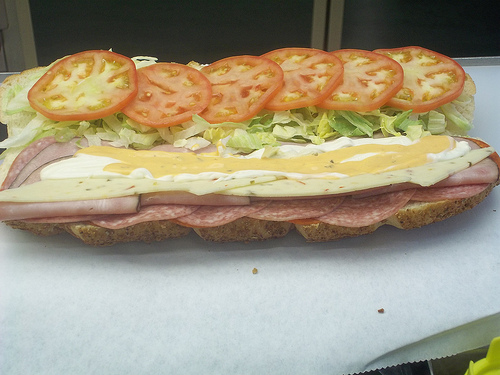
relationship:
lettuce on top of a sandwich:
[56, 115, 446, 128] [6, 32, 498, 291]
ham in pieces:
[9, 193, 478, 196] [6, 183, 156, 223]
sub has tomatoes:
[0, 51, 496, 261] [25, 24, 462, 127]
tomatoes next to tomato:
[25, 49, 135, 125] [116, 60, 217, 128]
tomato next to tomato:
[116, 60, 217, 128] [196, 49, 284, 133]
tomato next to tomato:
[196, 49, 284, 133] [260, 43, 342, 113]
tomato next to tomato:
[260, 43, 342, 113] [314, 36, 408, 122]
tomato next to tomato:
[314, 36, 408, 122] [374, 34, 474, 118]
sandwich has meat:
[6, 32, 498, 291] [18, 147, 500, 233]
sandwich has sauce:
[6, 32, 498, 291] [17, 137, 470, 166]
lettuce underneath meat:
[56, 115, 446, 128] [18, 147, 500, 233]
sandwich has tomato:
[6, 32, 498, 291] [374, 34, 474, 118]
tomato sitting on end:
[374, 34, 474, 118] [387, 27, 491, 208]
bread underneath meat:
[6, 135, 495, 254] [18, 147, 500, 233]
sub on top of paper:
[0, 51, 496, 261] [9, 59, 498, 374]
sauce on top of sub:
[17, 137, 470, 166] [0, 51, 496, 261]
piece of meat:
[9, 141, 144, 210] [18, 147, 500, 233]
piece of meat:
[143, 137, 264, 203] [18, 147, 500, 233]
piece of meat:
[351, 134, 491, 198] [18, 147, 500, 233]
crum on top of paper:
[229, 259, 307, 289] [9, 59, 498, 374]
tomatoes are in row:
[25, 24, 462, 127] [32, 39, 463, 129]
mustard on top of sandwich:
[95, 143, 462, 182] [6, 32, 498, 291]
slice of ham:
[12, 143, 139, 216] [9, 193, 478, 196]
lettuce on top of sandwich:
[56, 115, 446, 128] [6, 32, 498, 291]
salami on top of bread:
[34, 190, 480, 230] [6, 135, 495, 254]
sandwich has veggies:
[6, 32, 498, 291] [32, 55, 465, 135]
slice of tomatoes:
[29, 47, 143, 127] [25, 49, 135, 125]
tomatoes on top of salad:
[25, 49, 135, 125] [15, 72, 467, 135]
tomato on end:
[374, 34, 474, 118] [387, 27, 491, 208]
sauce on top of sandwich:
[17, 137, 470, 166] [6, 32, 498, 291]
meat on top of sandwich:
[18, 147, 500, 233] [6, 32, 498, 291]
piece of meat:
[249, 147, 365, 198] [18, 147, 500, 233]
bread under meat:
[6, 135, 495, 254] [18, 147, 500, 233]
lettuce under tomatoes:
[56, 115, 446, 128] [25, 24, 462, 127]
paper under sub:
[9, 59, 498, 374] [0, 51, 496, 261]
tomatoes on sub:
[25, 49, 135, 125] [0, 51, 496, 261]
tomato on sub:
[116, 60, 217, 128] [0, 51, 496, 261]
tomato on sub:
[196, 49, 284, 133] [0, 51, 496, 261]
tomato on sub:
[260, 43, 342, 113] [0, 51, 496, 261]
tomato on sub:
[314, 36, 408, 122] [0, 51, 496, 261]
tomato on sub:
[374, 34, 474, 118] [0, 51, 496, 261]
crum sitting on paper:
[229, 259, 307, 289] [9, 59, 498, 374]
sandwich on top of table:
[6, 32, 498, 291] [6, 49, 499, 375]